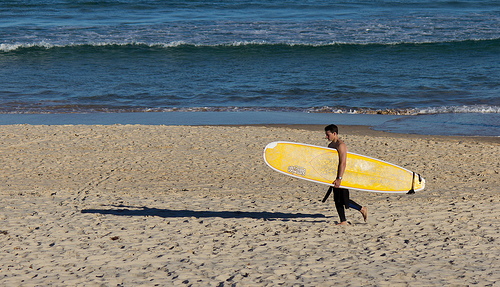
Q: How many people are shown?
A: One.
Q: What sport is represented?
A: Surfing.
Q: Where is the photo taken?
A: Beach.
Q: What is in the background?
A: Ocean.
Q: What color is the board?
A: Yellow.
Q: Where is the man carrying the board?
A: His left side.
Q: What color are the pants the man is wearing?
A: Black.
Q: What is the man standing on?
A: Sand.